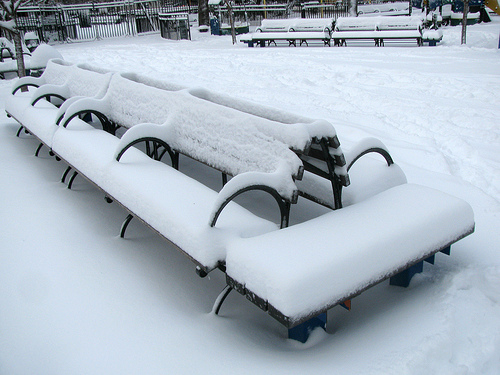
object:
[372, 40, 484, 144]
snow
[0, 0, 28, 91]
tree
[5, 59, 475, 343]
benches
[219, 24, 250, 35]
bin